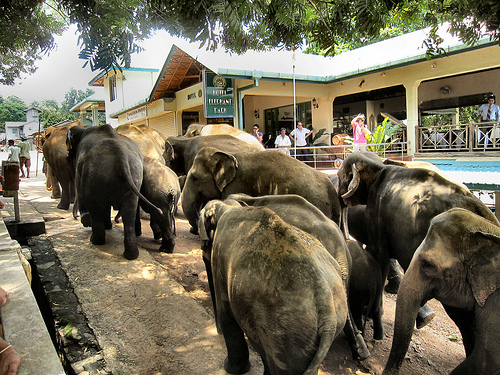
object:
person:
[350, 112, 368, 154]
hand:
[357, 113, 365, 121]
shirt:
[475, 104, 500, 120]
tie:
[485, 104, 492, 122]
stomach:
[213, 247, 315, 351]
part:
[245, 246, 275, 291]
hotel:
[111, 18, 500, 215]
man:
[477, 93, 500, 149]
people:
[251, 124, 264, 143]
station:
[51, 15, 498, 177]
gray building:
[1, 107, 44, 146]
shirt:
[290, 127, 311, 147]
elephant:
[134, 124, 168, 156]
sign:
[202, 68, 236, 118]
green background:
[201, 76, 236, 119]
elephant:
[63, 115, 156, 242]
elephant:
[44, 122, 85, 210]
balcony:
[417, 67, 499, 152]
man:
[275, 128, 291, 157]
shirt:
[273, 134, 291, 146]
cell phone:
[253, 124, 261, 132]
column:
[401, 81, 420, 155]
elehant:
[181, 146, 343, 235]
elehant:
[346, 239, 383, 341]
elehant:
[223, 192, 371, 359]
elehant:
[337, 151, 500, 329]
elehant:
[382, 206, 500, 375]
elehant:
[182, 123, 265, 153]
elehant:
[163, 134, 260, 176]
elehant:
[64, 124, 165, 260]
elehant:
[197, 198, 349, 375]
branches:
[2, 2, 495, 58]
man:
[288, 122, 314, 168]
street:
[1, 148, 500, 375]